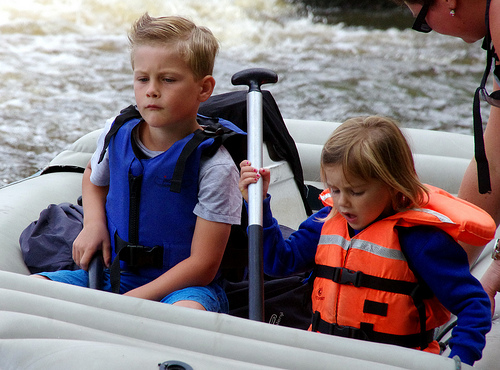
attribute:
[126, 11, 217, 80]
hair — blonde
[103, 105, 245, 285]
life jacket — blue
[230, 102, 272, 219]
handle — black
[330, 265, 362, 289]
clip — plastic, black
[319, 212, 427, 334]
vest — orange, life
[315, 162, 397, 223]
sunglasses — black, thick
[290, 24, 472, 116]
waves — white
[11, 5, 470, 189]
river — rapid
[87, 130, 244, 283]
shirt — grey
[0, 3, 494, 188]
water — turbulent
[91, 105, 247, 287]
jacket — life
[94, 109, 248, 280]
vest — blue, floater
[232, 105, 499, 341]
girl — young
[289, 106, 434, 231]
hair — blonde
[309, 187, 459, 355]
life vest — orange, black, silver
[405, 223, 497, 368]
blue sleeve — crinkled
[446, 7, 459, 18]
earring — small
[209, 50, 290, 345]
paddle — silver, black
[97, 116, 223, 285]
lifejacket — blue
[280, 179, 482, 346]
lifejacket — orange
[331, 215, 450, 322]
life jacket — orange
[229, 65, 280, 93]
handle — silver, gray, black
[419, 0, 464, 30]
face — her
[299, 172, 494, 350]
life vest — orange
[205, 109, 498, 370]
girl — little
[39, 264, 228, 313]
shorts — blue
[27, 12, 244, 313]
boy — young